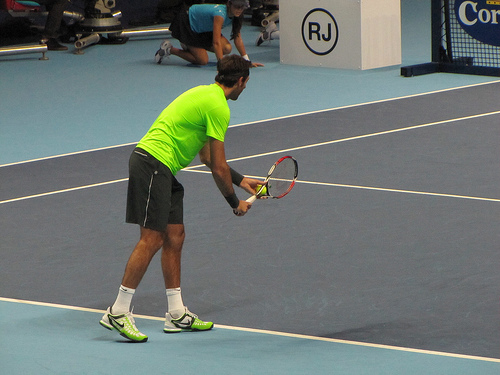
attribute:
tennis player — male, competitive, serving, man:
[101, 54, 267, 342]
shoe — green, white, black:
[99, 306, 148, 343]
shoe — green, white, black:
[164, 308, 214, 333]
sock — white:
[111, 284, 135, 314]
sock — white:
[165, 287, 183, 319]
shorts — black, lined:
[124, 147, 184, 233]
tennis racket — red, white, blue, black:
[233, 155, 300, 215]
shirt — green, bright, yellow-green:
[136, 83, 231, 177]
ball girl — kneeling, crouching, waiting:
[154, 0, 265, 68]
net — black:
[401, 0, 499, 78]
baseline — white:
[10, 80, 498, 168]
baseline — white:
[1, 296, 499, 363]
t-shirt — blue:
[189, 4, 234, 34]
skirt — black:
[168, 8, 223, 51]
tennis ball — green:
[255, 183, 269, 196]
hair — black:
[215, 54, 252, 89]